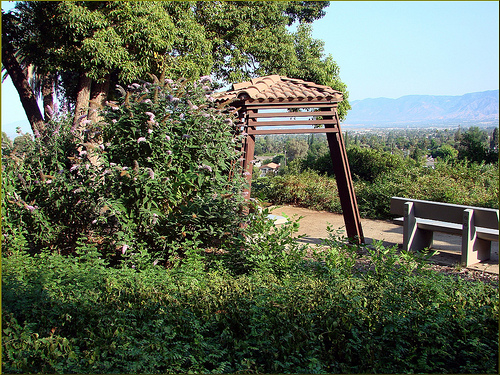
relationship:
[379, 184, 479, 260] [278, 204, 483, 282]
bench on a sidewalk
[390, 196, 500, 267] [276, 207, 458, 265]
bench on a sidewalk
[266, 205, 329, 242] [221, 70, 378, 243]
floor beneath structure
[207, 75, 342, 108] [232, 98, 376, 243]
roof on structure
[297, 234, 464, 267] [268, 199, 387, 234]
shadow on ground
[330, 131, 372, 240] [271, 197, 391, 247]
pillar on ground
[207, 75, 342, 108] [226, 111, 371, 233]
roof of structure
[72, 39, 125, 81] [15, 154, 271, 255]
branches of trees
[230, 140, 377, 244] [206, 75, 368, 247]
legs on pergola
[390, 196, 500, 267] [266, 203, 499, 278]
bench on sidewalk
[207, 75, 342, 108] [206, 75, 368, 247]
roof on pergola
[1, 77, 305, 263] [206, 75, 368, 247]
bush next to pergola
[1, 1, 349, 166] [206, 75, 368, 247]
trees behind pergola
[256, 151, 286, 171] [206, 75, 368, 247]
house below pergola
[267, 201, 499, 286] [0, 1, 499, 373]
sidewalk running through garden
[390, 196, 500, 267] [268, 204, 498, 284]
bench on path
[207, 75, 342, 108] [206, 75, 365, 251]
roof on pergola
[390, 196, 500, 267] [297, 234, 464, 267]
bench casting shadow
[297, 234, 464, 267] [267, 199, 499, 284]
shadow on ground